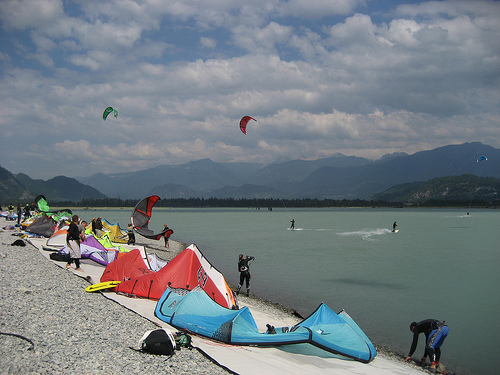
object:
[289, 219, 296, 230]
person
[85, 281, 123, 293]
surfboard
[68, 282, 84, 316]
ground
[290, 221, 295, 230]
wetsuit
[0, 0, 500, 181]
sky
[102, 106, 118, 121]
green kite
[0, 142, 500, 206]
mountains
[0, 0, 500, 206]
background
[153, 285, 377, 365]
kite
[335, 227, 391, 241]
white splashes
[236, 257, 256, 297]
black suit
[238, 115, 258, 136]
kite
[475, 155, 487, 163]
kites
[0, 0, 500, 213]
distance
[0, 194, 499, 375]
beach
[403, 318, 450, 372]
guy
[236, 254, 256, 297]
girl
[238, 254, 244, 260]
head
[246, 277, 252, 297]
leg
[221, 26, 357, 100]
clouds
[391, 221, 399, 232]
people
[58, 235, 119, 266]
kite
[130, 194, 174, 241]
kite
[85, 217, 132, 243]
kite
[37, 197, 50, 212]
kite